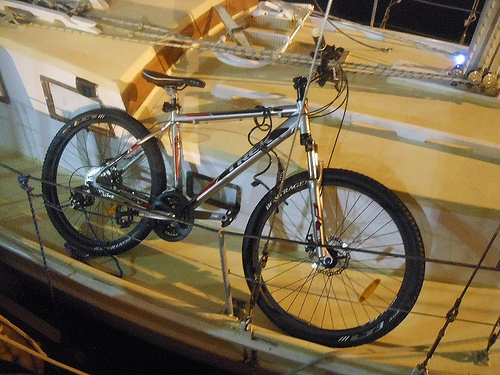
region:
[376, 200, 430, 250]
part of wheel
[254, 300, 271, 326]
edge of a wheel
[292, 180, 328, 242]
part of a metal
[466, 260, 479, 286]
part of a wire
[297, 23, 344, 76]
part of a steering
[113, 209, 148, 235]
part of a pedal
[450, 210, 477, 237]
part of a shadow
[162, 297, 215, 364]
edge of the boat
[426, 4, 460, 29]
part of a window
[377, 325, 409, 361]
surface of the boat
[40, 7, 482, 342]
Picture is taken outside.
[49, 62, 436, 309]
A bicycle is on the boat.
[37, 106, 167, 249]
The tires are black in color.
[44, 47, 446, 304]
The bicycle is on the deck of a boat.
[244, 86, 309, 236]
A lock is on the bicycle.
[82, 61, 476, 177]
The boat is light tan in color.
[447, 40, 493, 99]
This is part of the mast of the boat.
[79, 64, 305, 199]
The bike is silver, red and black in color.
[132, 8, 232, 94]
Wood paneling is on the boat.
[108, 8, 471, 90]
Rope is on the deck of the boat.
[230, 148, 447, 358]
bike tire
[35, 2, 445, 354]
bike on a boat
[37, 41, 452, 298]
orange black and silver bike sitting in boat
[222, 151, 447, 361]
black tire on black rim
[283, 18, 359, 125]
bike handlebars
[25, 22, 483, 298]
small boat with boat sitting on it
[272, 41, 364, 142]
bike brake cables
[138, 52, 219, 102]
thin flat bike seat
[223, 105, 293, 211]
TREK bike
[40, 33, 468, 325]
bike on the edge of a boat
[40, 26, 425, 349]
A silver mountain bike.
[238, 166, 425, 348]
A black bike tire.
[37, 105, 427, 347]
Two black bike tires.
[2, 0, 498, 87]
A rope tied to a boat.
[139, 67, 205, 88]
A black bike seat.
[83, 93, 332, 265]
A mountain bike frame.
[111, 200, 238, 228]
Two black bike peddles.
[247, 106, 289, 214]
A black bike lock.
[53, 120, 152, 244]
Spokes on a tire.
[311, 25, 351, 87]
Handlebars on a bike.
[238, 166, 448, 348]
front tire of bike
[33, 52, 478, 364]
silver bike on boat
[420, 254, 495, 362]
cables on side of boat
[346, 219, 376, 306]
spokes on bike tire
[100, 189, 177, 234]
pedal on side of bike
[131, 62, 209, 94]
black seat on bike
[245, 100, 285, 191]
cable lock on bike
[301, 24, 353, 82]
handlebar on front of bike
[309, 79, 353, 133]
black cables on bike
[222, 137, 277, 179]
bike brand on rod